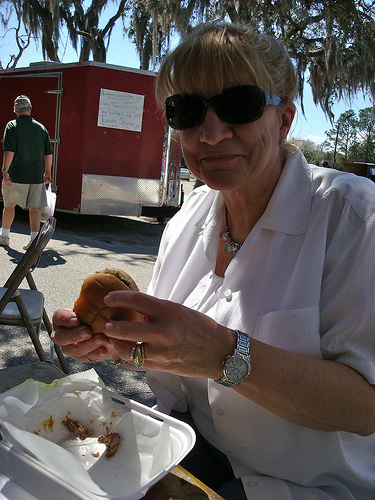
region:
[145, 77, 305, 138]
a black pair of sunglasses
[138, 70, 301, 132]
a pair of black sunglasses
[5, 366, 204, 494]
a white foam food container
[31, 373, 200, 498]
a foam box for takeout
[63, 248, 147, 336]
a pulled pork sandwich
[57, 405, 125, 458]
pieces of barbecue pork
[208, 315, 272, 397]
a silver wrist watch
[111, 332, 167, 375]
she is wearing gold rings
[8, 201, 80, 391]
a metal folding chair with a cushion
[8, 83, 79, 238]
this man is wearing a green shirt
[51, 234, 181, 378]
a woman holding a sandwich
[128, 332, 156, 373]
a woman wearing a set of rings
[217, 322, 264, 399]
a woman wearing a silver wrist watch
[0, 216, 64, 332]
a metal folding chair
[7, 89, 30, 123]
a man wearing a hat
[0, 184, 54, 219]
a man wearing shorts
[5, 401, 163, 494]
a plastic container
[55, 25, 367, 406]
This is a woman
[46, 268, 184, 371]
The woman is eating a sandwich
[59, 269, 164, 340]
The sandwich is on a hamburger bun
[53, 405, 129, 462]
Some of the meat from the sandwich fell out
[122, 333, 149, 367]
The woman is wearing multiple rings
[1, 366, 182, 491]
The food was served in a styrofoam container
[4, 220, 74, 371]
A folding chair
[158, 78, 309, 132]
The woman is wearing sunglasses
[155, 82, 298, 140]
sunglasses on the face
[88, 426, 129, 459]
hunk of meat in the container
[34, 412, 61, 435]
sauce stain on the side of the container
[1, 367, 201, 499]
white styrofoam container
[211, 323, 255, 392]
silver watch around the wrist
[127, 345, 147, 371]
ring around the finger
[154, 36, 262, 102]
bangs on the face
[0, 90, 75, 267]
man walking on the street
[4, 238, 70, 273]
shadow from the man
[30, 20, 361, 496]
A woman eating a sandwich.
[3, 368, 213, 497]
A white Styrofoam tray.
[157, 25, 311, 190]
A woman wearing sunglasses.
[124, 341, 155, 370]
Rings on the woman's left hand.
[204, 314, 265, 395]
A silver wristwatch on woman's left wrist.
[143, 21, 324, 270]
Woman wearing a silver necklace.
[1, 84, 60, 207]
A man wearing a green shirt.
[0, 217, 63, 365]
A folding chair.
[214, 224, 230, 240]
silver trinket on the ladies necklace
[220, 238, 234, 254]
silver trinket on the ladies necklace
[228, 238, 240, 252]
silver trinket on the ladies necklace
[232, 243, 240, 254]
silver trinket on the ladies necklace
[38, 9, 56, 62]
weepy branch on the big tree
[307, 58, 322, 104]
weepy branch on the big tree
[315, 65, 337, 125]
weepy branch on the big tree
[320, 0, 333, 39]
weepy branch on the big tree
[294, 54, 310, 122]
weepy branch on the big tree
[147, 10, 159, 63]
weepy branch on the big tree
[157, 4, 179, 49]
weepy branch on the big tree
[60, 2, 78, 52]
weepy branch on the big tree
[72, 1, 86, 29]
weepy branch on the big tree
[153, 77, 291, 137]
A pair of black sunglasses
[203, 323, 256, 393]
A watch around a wrist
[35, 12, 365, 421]
A woman holding a hamburger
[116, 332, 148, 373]
A ring around a finger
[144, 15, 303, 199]
Woman has blonde hair